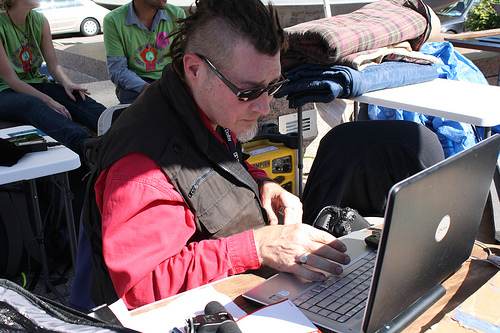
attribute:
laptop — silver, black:
[241, 133, 498, 332]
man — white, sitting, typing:
[69, 0, 352, 318]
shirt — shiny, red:
[93, 154, 261, 309]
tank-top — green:
[0, 8, 54, 92]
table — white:
[358, 78, 499, 126]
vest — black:
[71, 62, 271, 317]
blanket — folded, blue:
[274, 61, 440, 110]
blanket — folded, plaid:
[278, 0, 442, 71]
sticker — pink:
[156, 32, 170, 48]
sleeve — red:
[95, 153, 264, 311]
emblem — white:
[431, 213, 450, 243]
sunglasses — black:
[237, 78, 290, 101]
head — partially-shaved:
[184, 18, 283, 144]